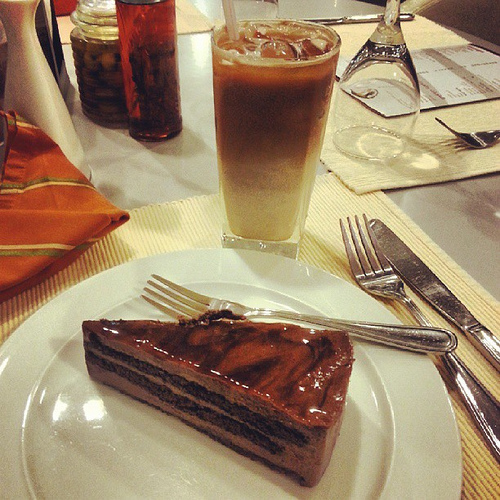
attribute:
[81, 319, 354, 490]
cake — chocolate, glazed, layered, triangle-shaped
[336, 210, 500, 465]
fork — silver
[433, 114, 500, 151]
fork — silver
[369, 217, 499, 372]
knife — silver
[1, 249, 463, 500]
plate — white, round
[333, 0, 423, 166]
wine glass — upside down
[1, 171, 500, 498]
place mat — yellow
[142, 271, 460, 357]
fork — silver